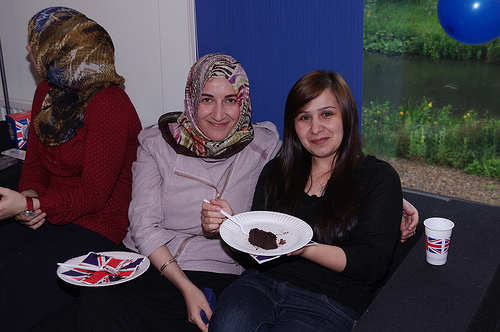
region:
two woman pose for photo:
[131, 41, 408, 330]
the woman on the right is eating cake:
[208, 59, 417, 330]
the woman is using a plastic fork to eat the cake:
[198, 55, 414, 330]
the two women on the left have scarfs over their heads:
[7, 0, 285, 330]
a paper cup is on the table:
[420, 210, 456, 265]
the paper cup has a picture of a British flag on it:
[420, 210, 456, 272]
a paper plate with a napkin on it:
[53, 242, 153, 293]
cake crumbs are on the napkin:
[52, 245, 151, 292]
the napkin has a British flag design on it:
[56, 245, 149, 291]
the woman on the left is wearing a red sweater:
[10, 0, 143, 260]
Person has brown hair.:
[291, 65, 370, 167]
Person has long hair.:
[278, 81, 383, 218]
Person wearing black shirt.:
[344, 209, 392, 295]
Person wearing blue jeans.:
[267, 287, 309, 327]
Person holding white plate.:
[250, 202, 298, 288]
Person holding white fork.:
[206, 176, 252, 254]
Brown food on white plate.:
[235, 211, 301, 291]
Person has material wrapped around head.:
[174, 59, 280, 199]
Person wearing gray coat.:
[155, 172, 222, 250]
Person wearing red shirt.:
[82, 127, 129, 224]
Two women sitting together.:
[153, 45, 383, 315]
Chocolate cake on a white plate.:
[197, 182, 315, 269]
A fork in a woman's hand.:
[195, 198, 247, 238]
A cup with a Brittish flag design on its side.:
[420, 200, 456, 275]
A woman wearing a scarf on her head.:
[170, 48, 250, 150]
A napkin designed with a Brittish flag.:
[66, 252, 136, 287]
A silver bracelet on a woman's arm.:
[155, 255, 177, 272]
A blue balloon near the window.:
[430, 0, 495, 45]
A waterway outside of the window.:
[362, 38, 473, 119]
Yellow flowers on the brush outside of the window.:
[393, 95, 458, 139]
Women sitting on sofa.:
[3, 13, 404, 330]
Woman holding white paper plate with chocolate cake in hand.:
[218, 211, 317, 259]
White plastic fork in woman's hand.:
[203, 196, 248, 236]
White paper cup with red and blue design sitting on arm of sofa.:
[423, 214, 456, 267]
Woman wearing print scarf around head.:
[170, 46, 255, 166]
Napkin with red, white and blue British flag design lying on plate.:
[61, 253, 148, 283]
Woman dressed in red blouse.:
[13, 83, 144, 245]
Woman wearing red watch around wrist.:
[17, 188, 37, 220]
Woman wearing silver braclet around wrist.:
[153, 251, 186, 276]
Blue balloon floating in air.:
[431, 0, 499, 67]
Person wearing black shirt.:
[318, 222, 386, 286]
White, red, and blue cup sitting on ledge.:
[413, 202, 466, 274]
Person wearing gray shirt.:
[134, 150, 216, 204]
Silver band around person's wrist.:
[155, 251, 192, 281]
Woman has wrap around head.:
[154, 58, 267, 166]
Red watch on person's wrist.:
[18, 184, 51, 235]